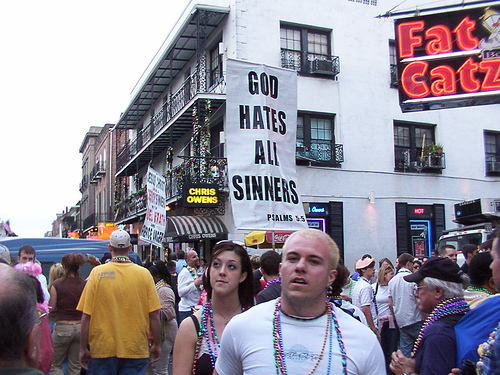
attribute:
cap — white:
[108, 226, 133, 251]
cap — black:
[397, 253, 471, 285]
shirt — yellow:
[73, 259, 166, 364]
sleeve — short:
[76, 264, 100, 318]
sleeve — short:
[144, 274, 164, 319]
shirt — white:
[210, 296, 388, 374]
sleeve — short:
[212, 317, 245, 375]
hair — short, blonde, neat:
[277, 227, 344, 273]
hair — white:
[418, 275, 465, 303]